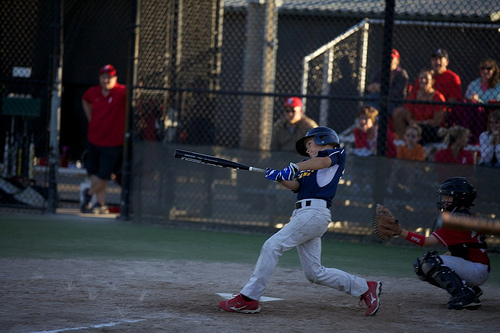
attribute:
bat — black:
[171, 148, 287, 182]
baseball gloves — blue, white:
[266, 162, 306, 183]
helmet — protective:
[289, 124, 344, 155]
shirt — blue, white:
[294, 149, 350, 204]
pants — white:
[240, 198, 371, 303]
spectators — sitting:
[350, 53, 499, 162]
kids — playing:
[148, 114, 497, 324]